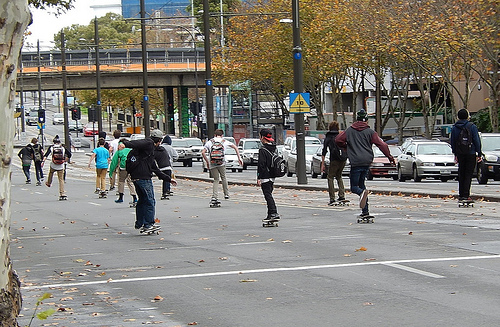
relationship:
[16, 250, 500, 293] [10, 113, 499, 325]
lanes drawn on street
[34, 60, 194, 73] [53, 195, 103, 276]
bridge over street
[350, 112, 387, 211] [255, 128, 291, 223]
person skateboarding by man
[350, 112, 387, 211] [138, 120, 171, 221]
person skateboarding by person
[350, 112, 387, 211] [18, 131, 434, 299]
person skateboarding down street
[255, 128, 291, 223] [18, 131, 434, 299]
man skateboarding down street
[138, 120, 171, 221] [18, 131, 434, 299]
person skateboarding down street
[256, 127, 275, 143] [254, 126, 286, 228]
cap worn on skateboarder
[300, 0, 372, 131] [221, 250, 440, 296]
tree bordering street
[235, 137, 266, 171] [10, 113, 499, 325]
cars driving down street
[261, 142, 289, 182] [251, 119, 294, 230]
backpack on skateboarder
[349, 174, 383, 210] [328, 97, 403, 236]
foot on skateboarder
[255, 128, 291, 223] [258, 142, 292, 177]
man with backpack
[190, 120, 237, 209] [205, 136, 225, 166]
person with backpack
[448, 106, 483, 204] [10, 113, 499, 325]
skateboarder in street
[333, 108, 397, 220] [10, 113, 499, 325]
person in street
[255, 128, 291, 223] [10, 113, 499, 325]
man in street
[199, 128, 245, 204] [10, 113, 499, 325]
person in street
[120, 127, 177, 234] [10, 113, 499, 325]
skateboarder in street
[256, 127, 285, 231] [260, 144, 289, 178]
man carrying backpack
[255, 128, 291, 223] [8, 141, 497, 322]
man skating down street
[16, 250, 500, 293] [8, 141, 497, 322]
lanes painted on street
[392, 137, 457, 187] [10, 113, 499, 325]
cars driving up street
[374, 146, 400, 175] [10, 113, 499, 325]
cars driving up street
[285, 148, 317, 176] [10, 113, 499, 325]
cars driving up street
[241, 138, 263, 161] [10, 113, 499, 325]
cars driving up street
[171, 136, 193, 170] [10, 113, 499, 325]
cars driving up street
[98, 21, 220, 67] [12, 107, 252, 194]
bridge over roadway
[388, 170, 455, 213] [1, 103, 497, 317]
divider between lanes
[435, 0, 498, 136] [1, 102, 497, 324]
tree lining roadway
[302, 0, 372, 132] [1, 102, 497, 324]
tree lining roadway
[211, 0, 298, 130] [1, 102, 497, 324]
tree lining roadway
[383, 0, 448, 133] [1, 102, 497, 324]
tree lining roadway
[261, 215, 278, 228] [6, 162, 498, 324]
skateboard on street